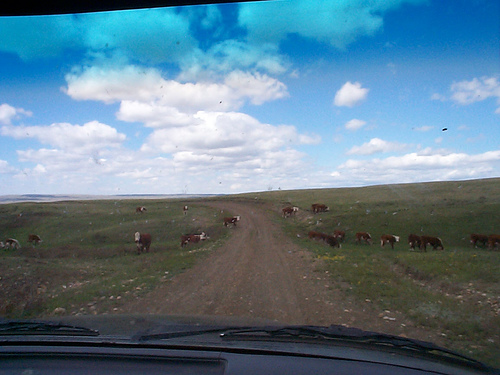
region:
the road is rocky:
[212, 255, 337, 329]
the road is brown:
[217, 224, 297, 309]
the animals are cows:
[132, 202, 220, 252]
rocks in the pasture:
[40, 272, 135, 320]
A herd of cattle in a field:
[7, 197, 498, 257]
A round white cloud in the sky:
[330, 79, 369, 112]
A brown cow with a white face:
[129, 231, 151, 251]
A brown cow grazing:
[420, 233, 445, 252]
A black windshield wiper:
[155, 322, 482, 362]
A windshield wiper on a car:
[1, 318, 108, 340]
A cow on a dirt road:
[220, 212, 242, 226]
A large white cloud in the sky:
[63, 65, 310, 187]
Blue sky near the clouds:
[397, 19, 477, 76]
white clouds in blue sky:
[22, 59, 54, 96]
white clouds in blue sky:
[307, 102, 338, 119]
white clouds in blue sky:
[360, 103, 454, 137]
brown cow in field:
[161, 215, 216, 255]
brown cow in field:
[312, 226, 350, 260]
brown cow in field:
[382, 218, 442, 259]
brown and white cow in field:
[124, 218, 155, 259]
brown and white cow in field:
[181, 222, 218, 244]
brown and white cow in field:
[218, 212, 242, 230]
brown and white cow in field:
[275, 205, 296, 222]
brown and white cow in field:
[312, 189, 332, 209]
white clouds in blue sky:
[95, 81, 153, 122]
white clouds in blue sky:
[318, 76, 353, 120]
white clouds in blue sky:
[208, 145, 246, 180]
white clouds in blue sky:
[248, 59, 286, 116]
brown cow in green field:
[121, 221, 151, 256]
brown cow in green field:
[187, 230, 207, 250]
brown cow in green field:
[302, 197, 327, 223]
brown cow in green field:
[355, 217, 370, 242]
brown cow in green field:
[378, 222, 394, 247]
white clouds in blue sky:
[319, 93, 340, 125]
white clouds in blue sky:
[388, 76, 425, 121]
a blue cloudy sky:
[2, 0, 498, 195]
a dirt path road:
[107, 197, 391, 332]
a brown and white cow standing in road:
[222, 213, 241, 226]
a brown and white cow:
[180, 232, 205, 245]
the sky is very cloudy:
[111, 67, 273, 160]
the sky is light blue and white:
[264, 70, 356, 160]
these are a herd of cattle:
[57, 205, 391, 284]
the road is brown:
[184, 227, 323, 327]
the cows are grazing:
[105, 193, 241, 270]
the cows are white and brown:
[96, 191, 250, 301]